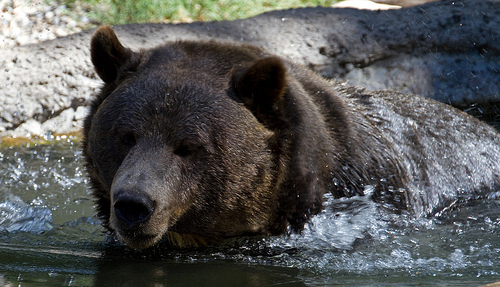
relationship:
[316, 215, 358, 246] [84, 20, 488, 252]
water next to bear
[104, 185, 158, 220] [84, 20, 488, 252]
nose of bear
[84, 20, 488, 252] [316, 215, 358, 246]
bear in water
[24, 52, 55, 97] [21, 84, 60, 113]
sunlight hitting rocks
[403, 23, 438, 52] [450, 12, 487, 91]
rocks in shadow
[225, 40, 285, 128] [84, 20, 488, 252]
ear of bear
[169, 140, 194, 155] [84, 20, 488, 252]
eye of bear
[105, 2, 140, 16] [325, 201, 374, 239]
grass next to pond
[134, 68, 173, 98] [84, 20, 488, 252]
fur of bear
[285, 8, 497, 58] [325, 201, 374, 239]
log in river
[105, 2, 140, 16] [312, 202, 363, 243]
grass on river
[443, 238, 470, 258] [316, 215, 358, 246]
drops of water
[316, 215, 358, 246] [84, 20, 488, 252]
water splashed by bear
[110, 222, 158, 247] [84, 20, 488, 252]
mouth of bear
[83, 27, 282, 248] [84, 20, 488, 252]
head of bear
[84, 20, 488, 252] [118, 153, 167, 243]
bear has snout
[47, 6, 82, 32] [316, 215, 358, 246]
ground by water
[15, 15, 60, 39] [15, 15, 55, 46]
side on side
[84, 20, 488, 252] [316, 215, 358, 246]
bear i water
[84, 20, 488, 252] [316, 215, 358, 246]
bear swimming water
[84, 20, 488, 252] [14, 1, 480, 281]
bear i picture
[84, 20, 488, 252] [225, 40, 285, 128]
bear has ear